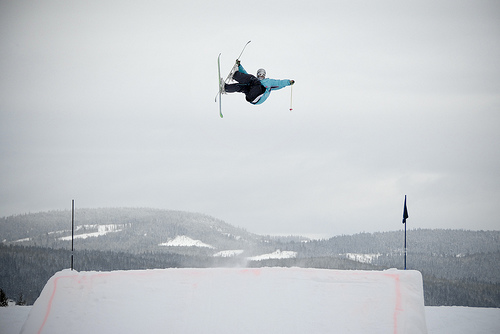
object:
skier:
[215, 40, 296, 118]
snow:
[0, 267, 499, 333]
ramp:
[18, 267, 430, 334]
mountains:
[0, 208, 500, 305]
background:
[0, 0, 499, 206]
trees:
[0, 221, 39, 296]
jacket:
[237, 64, 290, 105]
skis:
[215, 40, 252, 118]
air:
[13, 3, 196, 165]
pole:
[70, 199, 74, 269]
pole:
[402, 195, 409, 271]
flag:
[402, 195, 409, 224]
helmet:
[257, 68, 266, 77]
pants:
[224, 71, 265, 103]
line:
[393, 275, 403, 329]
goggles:
[257, 72, 266, 76]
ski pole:
[289, 85, 293, 111]